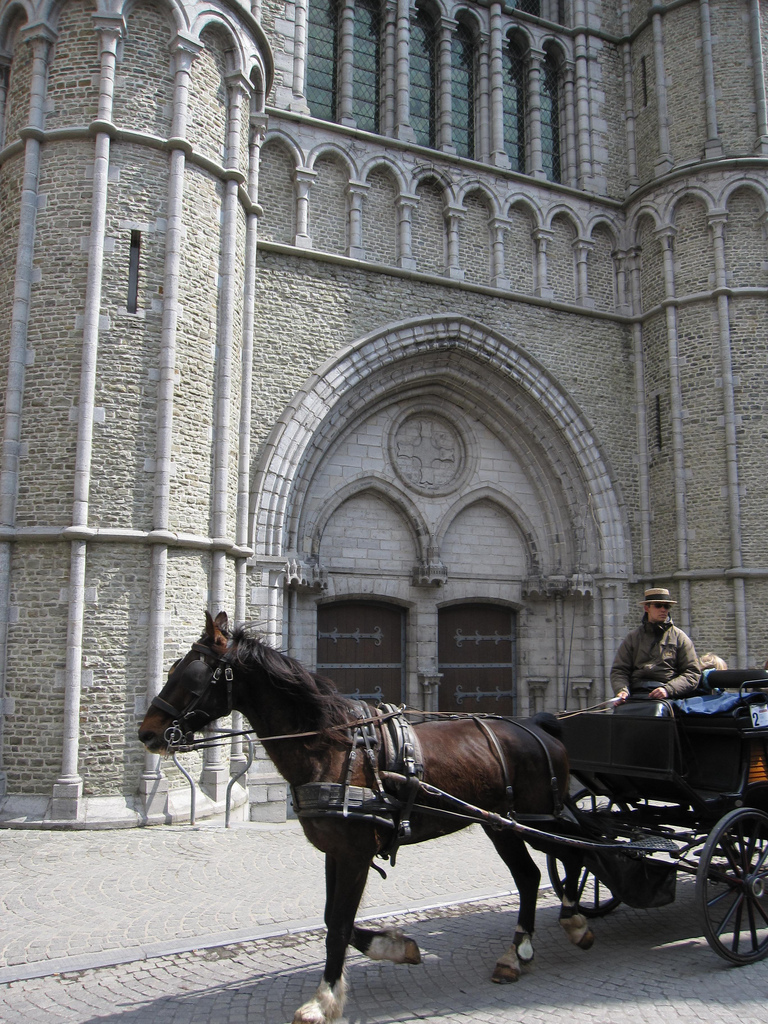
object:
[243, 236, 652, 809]
wall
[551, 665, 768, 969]
carriage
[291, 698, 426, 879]
harness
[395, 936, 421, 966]
hoof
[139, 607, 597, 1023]
horse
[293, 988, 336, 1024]
hoof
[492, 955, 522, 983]
hoof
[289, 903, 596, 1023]
hoofs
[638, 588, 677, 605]
hat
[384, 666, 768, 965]
carriage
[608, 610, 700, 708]
jacket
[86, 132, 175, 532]
wall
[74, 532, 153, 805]
wall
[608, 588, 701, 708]
human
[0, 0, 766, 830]
building